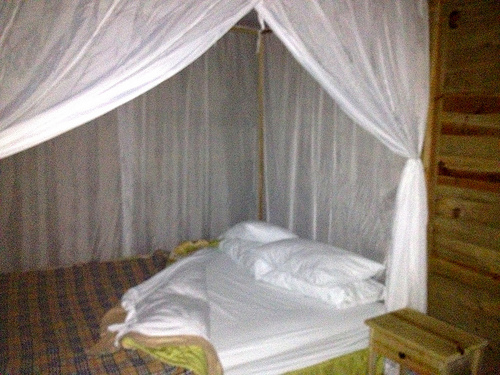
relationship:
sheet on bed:
[107, 247, 387, 375] [0, 215, 386, 373]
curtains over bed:
[1, 0, 436, 315] [0, 215, 386, 373]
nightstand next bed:
[365, 293, 496, 370] [0, 215, 386, 373]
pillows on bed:
[216, 220, 389, 311] [0, 215, 386, 373]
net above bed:
[1, 0, 428, 365] [0, 215, 386, 373]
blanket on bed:
[0, 248, 195, 374] [3, 232, 385, 374]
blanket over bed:
[95, 229, 265, 371] [31, 210, 366, 367]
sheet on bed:
[107, 247, 387, 375] [3, 232, 385, 374]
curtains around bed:
[1, 0, 436, 315] [0, 0, 432, 371]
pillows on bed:
[208, 209, 391, 315] [0, 215, 386, 373]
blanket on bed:
[0, 248, 195, 374] [0, 215, 386, 373]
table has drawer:
[365, 299, 490, 373] [365, 327, 450, 372]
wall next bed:
[420, 0, 499, 373] [0, 215, 386, 373]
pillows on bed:
[216, 220, 389, 311] [28, 228, 347, 366]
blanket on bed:
[0, 248, 195, 374] [7, 223, 365, 373]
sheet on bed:
[107, 247, 387, 375] [26, 257, 321, 373]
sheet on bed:
[156, 250, 242, 330] [19, 219, 393, 371]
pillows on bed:
[216, 220, 389, 311] [19, 238, 312, 373]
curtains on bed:
[0, 0, 430, 375] [19, 219, 393, 371]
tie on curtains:
[249, 18, 269, 50] [0, 0, 430, 375]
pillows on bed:
[208, 209, 391, 315] [0, 0, 432, 371]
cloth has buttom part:
[385, 155, 462, 325] [384, 151, 444, 320]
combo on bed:
[2, 214, 385, 372] [0, 215, 386, 373]